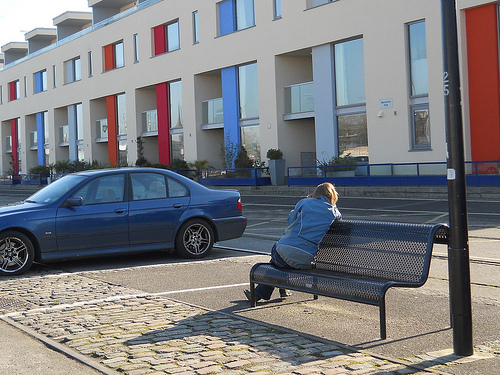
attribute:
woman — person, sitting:
[245, 181, 342, 305]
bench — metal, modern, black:
[250, 215, 453, 342]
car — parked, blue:
[1, 166, 247, 275]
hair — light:
[308, 182, 341, 208]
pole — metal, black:
[441, 3, 475, 358]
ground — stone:
[3, 268, 446, 372]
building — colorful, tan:
[1, 2, 499, 193]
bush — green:
[232, 146, 255, 178]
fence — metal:
[14, 163, 500, 189]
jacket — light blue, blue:
[276, 195, 345, 257]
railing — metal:
[287, 158, 500, 171]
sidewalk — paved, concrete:
[220, 230, 500, 287]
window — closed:
[73, 170, 126, 205]